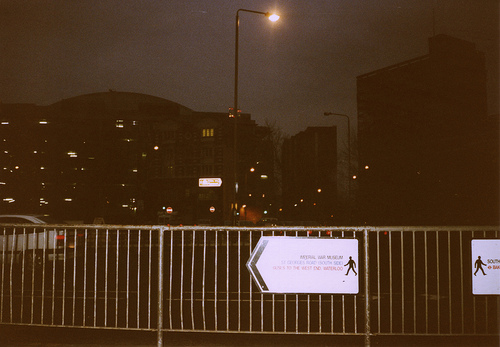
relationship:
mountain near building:
[49, 85, 194, 115] [174, 114, 235, 225]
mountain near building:
[49, 85, 194, 115] [279, 122, 338, 216]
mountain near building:
[49, 85, 194, 115] [2, 115, 55, 141]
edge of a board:
[282, 225, 314, 239] [226, 228, 365, 299]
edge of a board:
[259, 284, 299, 306] [259, 287, 362, 293]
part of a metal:
[145, 254, 212, 344] [149, 225, 234, 331]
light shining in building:
[37, 120, 47, 125] [2, 96, 278, 227]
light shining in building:
[151, 144, 158, 150] [2, 96, 278, 227]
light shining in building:
[248, 165, 256, 172] [277, 122, 339, 222]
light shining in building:
[291, 202, 297, 205] [277, 122, 339, 222]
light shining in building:
[361, 163, 369, 170] [351, 28, 483, 222]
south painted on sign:
[480, 258, 485, 262] [469, 235, 499, 295]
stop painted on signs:
[165, 207, 172, 212] [165, 206, 173, 214]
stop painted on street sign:
[208, 207, 215, 209] [208, 204, 216, 213]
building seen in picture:
[2, 96, 278, 227] [1, 1, 483, 343]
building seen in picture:
[277, 122, 339, 222] [1, 1, 483, 343]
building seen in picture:
[351, 28, 483, 222] [1, 1, 483, 343]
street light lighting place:
[233, 7, 280, 224] [2, 94, 277, 227]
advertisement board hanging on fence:
[242, 234, 360, 295] [0, 224, 500, 346]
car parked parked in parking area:
[7, 201, 65, 264] [2, 239, 482, 289]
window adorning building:
[200, 126, 215, 138] [5, 88, 275, 223]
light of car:
[55, 237, 65, 244] [1, 204, 79, 260]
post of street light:
[229, 5, 265, 226] [264, 10, 283, 24]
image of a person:
[344, 254, 359, 275] [344, 253, 358, 282]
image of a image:
[343, 255, 358, 276] [343, 255, 358, 276]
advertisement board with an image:
[244, 234, 362, 295] [341, 255, 359, 279]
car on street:
[7, 202, 79, 283] [0, 209, 397, 291]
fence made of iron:
[3, 226, 497, 338] [29, 221, 39, 316]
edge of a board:
[265, 287, 360, 303] [239, 224, 383, 315]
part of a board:
[297, 280, 317, 289] [246, 235, 358, 292]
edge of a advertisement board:
[279, 288, 344, 298] [244, 234, 362, 295]